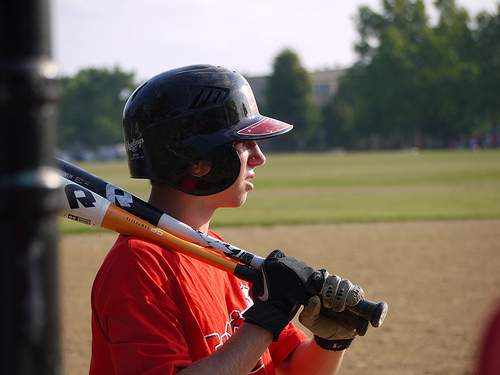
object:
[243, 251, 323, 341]
glove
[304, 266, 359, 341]
glove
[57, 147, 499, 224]
field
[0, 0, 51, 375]
pole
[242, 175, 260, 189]
mouth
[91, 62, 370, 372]
he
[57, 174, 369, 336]
bat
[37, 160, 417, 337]
bats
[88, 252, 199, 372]
top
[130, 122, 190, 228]
shadow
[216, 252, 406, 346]
gloves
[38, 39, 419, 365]
baseball game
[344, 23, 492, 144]
trees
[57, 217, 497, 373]
dirt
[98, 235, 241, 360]
jersey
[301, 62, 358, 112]
tan-colored building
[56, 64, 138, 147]
tree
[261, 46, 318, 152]
tree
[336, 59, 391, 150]
tree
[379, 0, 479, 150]
tree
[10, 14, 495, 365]
scene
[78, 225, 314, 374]
shirt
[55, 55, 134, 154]
tree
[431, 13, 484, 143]
tree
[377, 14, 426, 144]
tree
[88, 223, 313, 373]
uniform top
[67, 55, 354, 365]
boy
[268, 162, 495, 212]
grass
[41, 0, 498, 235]
plants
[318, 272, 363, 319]
grey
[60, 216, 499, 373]
ground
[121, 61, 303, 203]
helmet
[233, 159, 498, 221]
soil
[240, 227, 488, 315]
turf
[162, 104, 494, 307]
background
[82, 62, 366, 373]
player